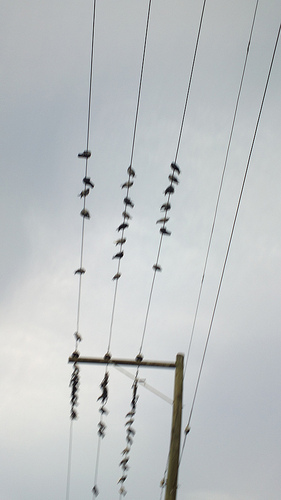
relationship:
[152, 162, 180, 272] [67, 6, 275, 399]
bird on power lines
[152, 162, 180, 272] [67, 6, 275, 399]
bird sitting on power lines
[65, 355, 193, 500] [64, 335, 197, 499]
wooden base of electric pole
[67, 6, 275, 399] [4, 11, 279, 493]
power lines in sky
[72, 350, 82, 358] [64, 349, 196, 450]
black object on power line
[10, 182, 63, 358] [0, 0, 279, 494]
white misty cloud in sky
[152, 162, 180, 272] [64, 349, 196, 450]
bird sitting on power line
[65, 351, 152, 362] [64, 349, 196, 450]
black connectors between power line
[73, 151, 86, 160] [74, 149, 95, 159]
tail of bird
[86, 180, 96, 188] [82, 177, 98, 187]
tail of bird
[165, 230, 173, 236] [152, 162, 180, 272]
tail of bird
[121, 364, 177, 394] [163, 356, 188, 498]
striation mark on pole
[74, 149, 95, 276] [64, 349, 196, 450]
bird on power line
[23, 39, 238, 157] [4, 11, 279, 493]
clouds in sky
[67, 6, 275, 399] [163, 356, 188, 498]
power lines on pole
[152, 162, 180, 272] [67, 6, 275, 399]
bird on lines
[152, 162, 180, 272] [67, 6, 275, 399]
bird sitting on lines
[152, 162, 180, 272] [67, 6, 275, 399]
bird sitting together lines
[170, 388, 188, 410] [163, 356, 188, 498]
splinters on wood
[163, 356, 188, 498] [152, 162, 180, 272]
electical post near bird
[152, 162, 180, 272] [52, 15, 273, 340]
bird on wire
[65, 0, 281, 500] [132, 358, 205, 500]
power lines connected to post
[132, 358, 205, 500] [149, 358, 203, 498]
post made of wood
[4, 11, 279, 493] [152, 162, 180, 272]
sky above bird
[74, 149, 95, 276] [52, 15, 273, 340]
bird on wire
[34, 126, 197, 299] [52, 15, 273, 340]
group of birds on wire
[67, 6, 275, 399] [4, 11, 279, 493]
black wire below sky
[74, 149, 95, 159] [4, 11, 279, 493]
bird above sky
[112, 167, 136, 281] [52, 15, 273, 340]
bird on wire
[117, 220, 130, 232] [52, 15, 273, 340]
bird on wire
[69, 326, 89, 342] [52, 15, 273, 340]
bird on wire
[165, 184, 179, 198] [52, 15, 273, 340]
bird on wire